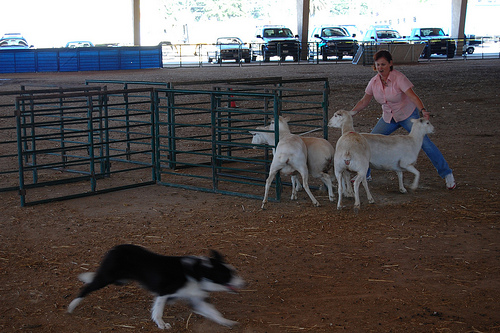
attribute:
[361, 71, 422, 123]
shirt — pink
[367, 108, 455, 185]
jeans — blue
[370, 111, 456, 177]
jeans — blue